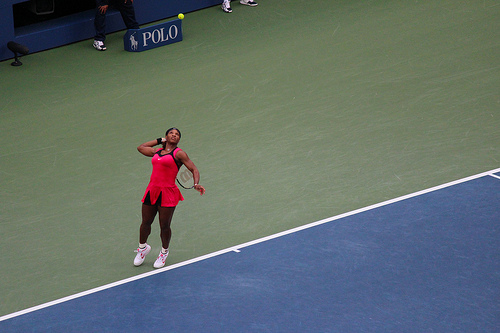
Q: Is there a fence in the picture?
A: No, there are no fences.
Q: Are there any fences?
A: No, there are no fences.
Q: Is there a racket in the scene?
A: Yes, there is a racket.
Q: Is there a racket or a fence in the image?
A: Yes, there is a racket.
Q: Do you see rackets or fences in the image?
A: Yes, there is a racket.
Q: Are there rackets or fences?
A: Yes, there is a racket.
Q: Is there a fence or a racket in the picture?
A: Yes, there is a racket.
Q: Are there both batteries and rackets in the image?
A: No, there is a racket but no batteries.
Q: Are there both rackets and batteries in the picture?
A: No, there is a racket but no batteries.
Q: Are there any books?
A: No, there are no books.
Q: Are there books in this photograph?
A: No, there are no books.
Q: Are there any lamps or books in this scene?
A: No, there are no books or lamps.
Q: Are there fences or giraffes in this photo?
A: No, there are no fences or giraffes.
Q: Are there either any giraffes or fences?
A: No, there are no fences or giraffes.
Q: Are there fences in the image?
A: No, there are no fences.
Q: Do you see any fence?
A: No, there are no fences.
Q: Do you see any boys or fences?
A: No, there are no fences or boys.